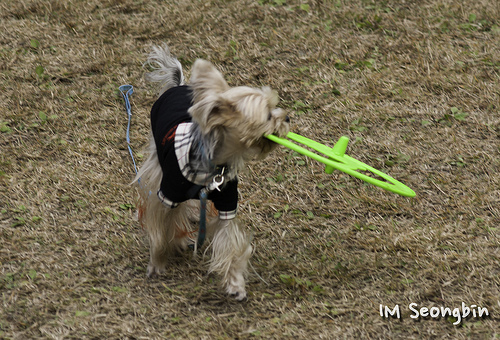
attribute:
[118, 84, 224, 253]
leash — blue, silver, turquoise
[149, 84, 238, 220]
sweater — black, plaid, long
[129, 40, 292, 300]
dog — small, little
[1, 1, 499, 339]
grass — green, brown, dry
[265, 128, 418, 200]
toy — green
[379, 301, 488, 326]
lettering — white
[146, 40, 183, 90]
tail — fluffy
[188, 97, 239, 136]
ears — shaggy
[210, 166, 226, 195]
clip — silver